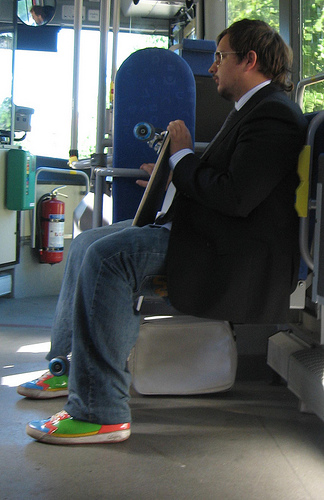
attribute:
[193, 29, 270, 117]
man — sitting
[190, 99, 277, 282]
coat — black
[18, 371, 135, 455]
sneakers — colorful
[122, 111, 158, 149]
wheels — blue